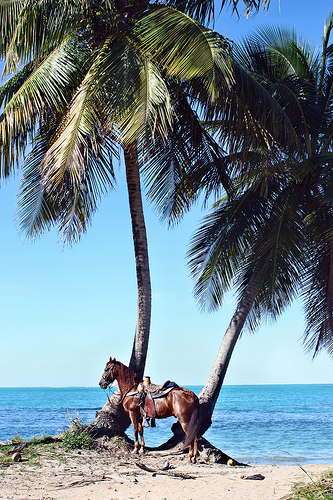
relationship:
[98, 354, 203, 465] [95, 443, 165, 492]
horse on sand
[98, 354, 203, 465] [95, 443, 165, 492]
horse in sand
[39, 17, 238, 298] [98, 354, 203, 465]
tree near horse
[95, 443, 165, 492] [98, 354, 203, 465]
sand below horse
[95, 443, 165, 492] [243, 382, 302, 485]
sand near water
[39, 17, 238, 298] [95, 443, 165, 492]
tree in sand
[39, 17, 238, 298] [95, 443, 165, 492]
tree on sand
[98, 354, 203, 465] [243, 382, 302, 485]
horse near water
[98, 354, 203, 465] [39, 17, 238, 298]
horse near tree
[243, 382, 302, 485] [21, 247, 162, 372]
water below sky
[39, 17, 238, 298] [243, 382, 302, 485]
tree near water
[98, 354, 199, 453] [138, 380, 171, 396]
horse with saddle